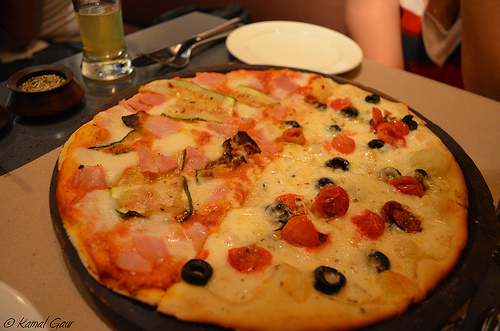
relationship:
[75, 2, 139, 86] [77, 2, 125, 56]
glass with beer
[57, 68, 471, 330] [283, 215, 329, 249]
pizza with pepperoni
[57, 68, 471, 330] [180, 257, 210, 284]
pizza with olives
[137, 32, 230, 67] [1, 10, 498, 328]
fork on table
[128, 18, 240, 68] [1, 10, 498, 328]
knife on table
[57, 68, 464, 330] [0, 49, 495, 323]
pizza on table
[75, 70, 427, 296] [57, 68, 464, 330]
toppings on pizza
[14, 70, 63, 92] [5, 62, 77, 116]
spices in bowl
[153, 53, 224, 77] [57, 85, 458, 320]
fork for pizza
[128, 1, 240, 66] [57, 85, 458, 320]
knife for pizza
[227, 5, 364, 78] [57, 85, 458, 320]
plate for pizza